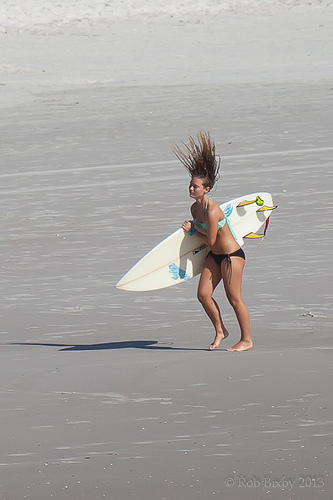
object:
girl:
[169, 129, 253, 353]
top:
[193, 180, 237, 240]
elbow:
[204, 236, 217, 246]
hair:
[170, 130, 221, 192]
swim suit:
[193, 179, 245, 266]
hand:
[181, 220, 194, 233]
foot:
[209, 328, 230, 350]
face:
[189, 178, 204, 197]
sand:
[37, 333, 139, 404]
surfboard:
[113, 192, 274, 294]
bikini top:
[193, 180, 238, 240]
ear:
[204, 187, 210, 193]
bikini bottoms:
[206, 247, 245, 264]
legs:
[220, 256, 249, 336]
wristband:
[189, 228, 195, 236]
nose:
[190, 186, 194, 191]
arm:
[193, 210, 218, 246]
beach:
[8, 4, 333, 500]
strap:
[244, 215, 270, 238]